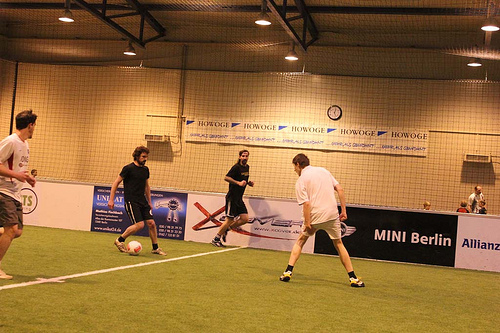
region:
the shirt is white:
[291, 168, 342, 237]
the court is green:
[191, 258, 251, 330]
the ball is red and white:
[118, 233, 148, 257]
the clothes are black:
[110, 160, 166, 227]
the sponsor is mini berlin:
[362, 216, 451, 263]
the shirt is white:
[4, 130, 29, 202]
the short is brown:
[1, 195, 26, 225]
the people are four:
[11, 105, 347, 294]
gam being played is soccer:
[3, 70, 495, 305]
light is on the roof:
[240, 11, 318, 87]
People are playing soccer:
[1, 110, 365, 285]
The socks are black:
[286, 264, 355, 279]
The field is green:
[102, 278, 303, 321]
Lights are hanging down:
[57, 10, 497, 66]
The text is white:
[373, 227, 452, 247]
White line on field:
[0, 246, 242, 291]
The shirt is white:
[295, 166, 337, 221]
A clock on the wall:
[326, 103, 341, 120]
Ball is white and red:
[127, 239, 140, 254]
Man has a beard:
[137, 156, 149, 165]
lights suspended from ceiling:
[57, 0, 499, 67]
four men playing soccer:
[0, 108, 362, 281]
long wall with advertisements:
[25, 176, 499, 273]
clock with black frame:
[326, 103, 342, 121]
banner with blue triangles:
[181, 115, 428, 159]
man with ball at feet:
[110, 145, 162, 255]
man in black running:
[213, 149, 254, 245]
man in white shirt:
[281, 153, 364, 288]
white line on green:
[0, 222, 278, 332]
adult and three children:
[420, 185, 486, 215]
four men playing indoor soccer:
[0, 106, 369, 289]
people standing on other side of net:
[420, 184, 488, 217]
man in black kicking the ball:
[106, 144, 167, 256]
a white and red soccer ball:
[124, 238, 142, 255]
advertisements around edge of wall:
[18, 176, 498, 273]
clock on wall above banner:
[325, 103, 343, 120]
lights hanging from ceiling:
[55, 13, 498, 70]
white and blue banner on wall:
[181, 115, 432, 159]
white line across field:
[0, 243, 250, 293]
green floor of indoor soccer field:
[1, 223, 498, 331]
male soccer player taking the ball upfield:
[106, 143, 168, 259]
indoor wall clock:
[325, 103, 342, 119]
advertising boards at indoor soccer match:
[16, 178, 498, 275]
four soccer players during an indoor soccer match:
[1, 2, 496, 331]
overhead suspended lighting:
[49, 1, 498, 73]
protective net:
[6, 54, 499, 216]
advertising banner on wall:
[182, 111, 429, 157]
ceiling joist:
[261, 1, 321, 54]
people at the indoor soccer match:
[421, 185, 493, 212]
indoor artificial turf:
[1, 213, 499, 331]